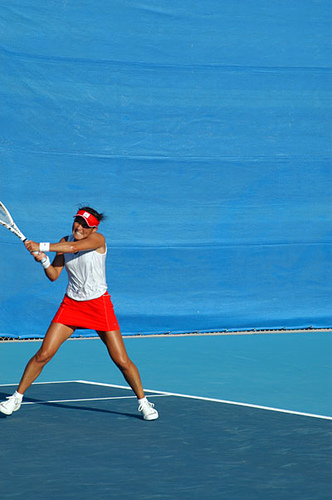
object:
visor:
[73, 208, 97, 227]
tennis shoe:
[134, 395, 160, 425]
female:
[0, 205, 158, 422]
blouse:
[64, 234, 107, 301]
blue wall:
[0, 0, 332, 340]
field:
[0, 326, 328, 498]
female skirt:
[49, 288, 119, 335]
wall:
[2, 2, 331, 333]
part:
[185, 440, 234, 487]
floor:
[0, 330, 331, 499]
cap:
[72, 209, 99, 227]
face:
[72, 218, 91, 239]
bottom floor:
[1, 378, 332, 499]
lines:
[70, 377, 330, 421]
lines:
[0, 377, 78, 385]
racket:
[0, 199, 45, 265]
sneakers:
[0, 390, 24, 415]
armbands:
[37, 239, 49, 255]